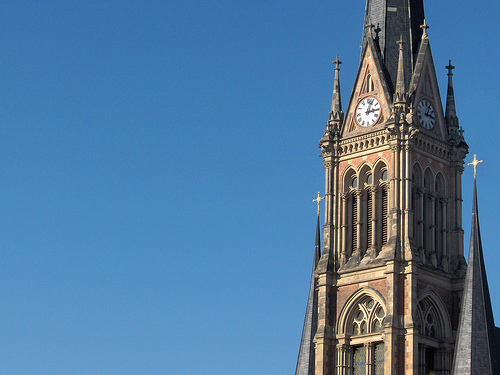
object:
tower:
[294, 2, 500, 375]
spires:
[296, 187, 326, 375]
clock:
[354, 95, 384, 128]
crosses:
[311, 191, 326, 217]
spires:
[407, 17, 451, 143]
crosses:
[331, 55, 345, 72]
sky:
[3, 1, 500, 374]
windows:
[350, 342, 369, 374]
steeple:
[352, 0, 434, 87]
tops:
[320, 0, 467, 167]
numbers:
[357, 116, 365, 126]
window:
[370, 339, 387, 374]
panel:
[341, 28, 395, 138]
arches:
[370, 156, 389, 189]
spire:
[452, 156, 500, 375]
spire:
[391, 33, 410, 103]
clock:
[416, 98, 438, 131]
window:
[425, 343, 441, 375]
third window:
[342, 156, 391, 194]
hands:
[367, 106, 383, 115]